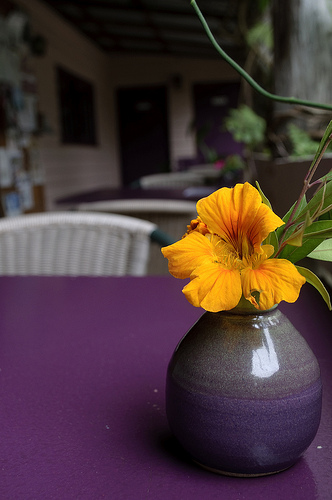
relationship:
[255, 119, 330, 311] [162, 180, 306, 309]
leaves by flower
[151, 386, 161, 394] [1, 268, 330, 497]
crumb on tablecloth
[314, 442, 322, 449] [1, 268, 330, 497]
crumb on tablecloth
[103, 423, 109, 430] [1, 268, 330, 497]
crumb on tablecloth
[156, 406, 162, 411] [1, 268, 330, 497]
crumb on tablecloth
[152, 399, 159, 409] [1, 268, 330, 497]
crumb on tablecloth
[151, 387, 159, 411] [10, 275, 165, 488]
crumbs on table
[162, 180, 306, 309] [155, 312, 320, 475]
flower in a vase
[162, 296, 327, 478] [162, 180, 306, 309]
vase for a flower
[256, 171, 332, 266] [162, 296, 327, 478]
leaf in vase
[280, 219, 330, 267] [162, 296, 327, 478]
leaf in vase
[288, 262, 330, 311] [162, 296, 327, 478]
leaf in vase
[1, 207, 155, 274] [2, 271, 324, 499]
chair next to table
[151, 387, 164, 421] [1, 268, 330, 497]
crumbs on tablecloth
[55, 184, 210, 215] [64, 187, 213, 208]
tablecloth on table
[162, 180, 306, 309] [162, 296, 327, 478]
flower in vase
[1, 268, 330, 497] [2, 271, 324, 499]
tablecloth covering table